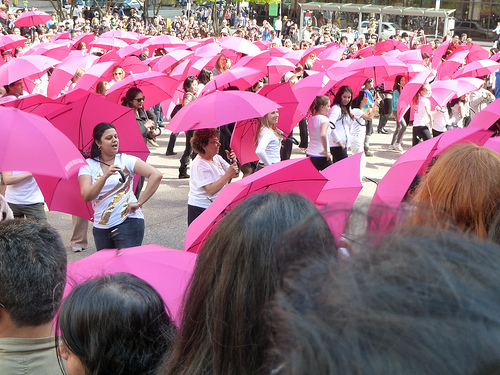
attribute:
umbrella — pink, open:
[182, 85, 282, 138]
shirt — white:
[90, 163, 141, 227]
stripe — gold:
[89, 167, 130, 205]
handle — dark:
[95, 158, 134, 186]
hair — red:
[437, 152, 486, 225]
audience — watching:
[75, 15, 415, 44]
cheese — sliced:
[495, 3, 497, 6]